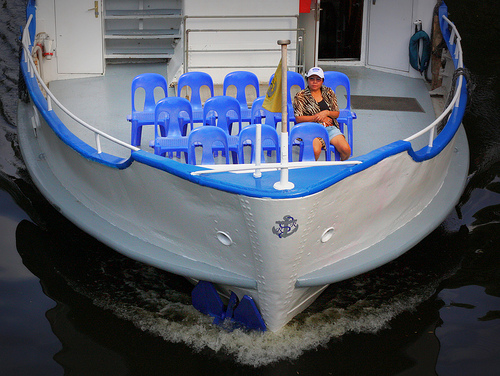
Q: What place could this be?
A: It is a river.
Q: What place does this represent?
A: It represents the river.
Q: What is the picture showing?
A: It is showing a river.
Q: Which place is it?
A: It is a river.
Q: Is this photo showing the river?
A: Yes, it is showing the river.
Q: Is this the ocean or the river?
A: It is the river.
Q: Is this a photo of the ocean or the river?
A: It is showing the river.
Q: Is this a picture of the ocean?
A: No, the picture is showing the river.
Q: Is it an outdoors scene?
A: Yes, it is outdoors.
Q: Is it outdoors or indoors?
A: It is outdoors.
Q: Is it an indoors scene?
A: No, it is outdoors.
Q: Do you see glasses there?
A: No, there are no glasses.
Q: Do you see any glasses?
A: No, there are no glasses.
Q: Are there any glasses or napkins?
A: No, there are no glasses or napkins.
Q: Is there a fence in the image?
A: No, there are no fences.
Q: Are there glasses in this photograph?
A: No, there are no glasses.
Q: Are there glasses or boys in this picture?
A: No, there are no glasses or boys.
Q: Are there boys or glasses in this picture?
A: No, there are no glasses or boys.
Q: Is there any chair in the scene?
A: Yes, there is a chair.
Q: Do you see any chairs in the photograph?
A: Yes, there is a chair.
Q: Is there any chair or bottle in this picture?
A: Yes, there is a chair.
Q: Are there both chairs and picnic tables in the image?
A: No, there is a chair but no picnic tables.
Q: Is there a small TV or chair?
A: Yes, there is a small chair.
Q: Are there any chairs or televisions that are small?
A: Yes, the chair is small.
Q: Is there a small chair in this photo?
A: Yes, there is a small chair.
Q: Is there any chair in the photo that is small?
A: Yes, there is a chair that is small.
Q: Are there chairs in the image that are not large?
A: Yes, there is a small chair.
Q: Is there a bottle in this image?
A: No, there are no bottles.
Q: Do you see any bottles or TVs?
A: No, there are no bottles or tvs.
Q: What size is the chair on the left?
A: The chair is small.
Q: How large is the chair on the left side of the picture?
A: The chair is small.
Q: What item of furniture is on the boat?
A: The piece of furniture is a chair.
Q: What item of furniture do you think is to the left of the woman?
A: The piece of furniture is a chair.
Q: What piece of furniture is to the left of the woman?
A: The piece of furniture is a chair.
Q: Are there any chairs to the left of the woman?
A: Yes, there is a chair to the left of the woman.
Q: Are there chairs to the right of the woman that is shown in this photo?
A: No, the chair is to the left of the woman.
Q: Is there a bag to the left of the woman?
A: No, there is a chair to the left of the woman.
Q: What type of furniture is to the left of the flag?
A: The piece of furniture is a chair.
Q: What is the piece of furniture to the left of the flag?
A: The piece of furniture is a chair.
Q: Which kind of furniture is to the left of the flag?
A: The piece of furniture is a chair.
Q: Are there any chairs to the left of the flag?
A: Yes, there is a chair to the left of the flag.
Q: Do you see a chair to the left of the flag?
A: Yes, there is a chair to the left of the flag.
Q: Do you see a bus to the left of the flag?
A: No, there is a chair to the left of the flag.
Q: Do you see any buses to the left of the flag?
A: No, there is a chair to the left of the flag.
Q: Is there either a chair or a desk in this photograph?
A: Yes, there is a chair.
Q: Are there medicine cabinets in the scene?
A: No, there are no medicine cabinets.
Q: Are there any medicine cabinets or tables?
A: No, there are no medicine cabinets or tables.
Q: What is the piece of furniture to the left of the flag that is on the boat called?
A: The piece of furniture is a chair.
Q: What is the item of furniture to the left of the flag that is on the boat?
A: The piece of furniture is a chair.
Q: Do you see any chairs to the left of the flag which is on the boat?
A: Yes, there is a chair to the left of the flag.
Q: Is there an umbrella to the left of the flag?
A: No, there is a chair to the left of the flag.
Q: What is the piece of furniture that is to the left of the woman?
A: The piece of furniture is a chair.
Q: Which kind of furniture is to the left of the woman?
A: The piece of furniture is a chair.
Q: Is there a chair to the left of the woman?
A: Yes, there is a chair to the left of the woman.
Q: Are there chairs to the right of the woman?
A: No, the chair is to the left of the woman.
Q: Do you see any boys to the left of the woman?
A: No, there is a chair to the left of the woman.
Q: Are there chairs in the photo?
A: Yes, there is a chair.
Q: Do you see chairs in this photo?
A: Yes, there is a chair.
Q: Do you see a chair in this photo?
A: Yes, there is a chair.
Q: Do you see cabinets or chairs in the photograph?
A: Yes, there is a chair.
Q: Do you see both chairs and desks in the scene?
A: No, there is a chair but no desks.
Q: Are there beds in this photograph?
A: No, there are no beds.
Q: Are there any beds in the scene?
A: No, there are no beds.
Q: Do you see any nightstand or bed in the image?
A: No, there are no beds or nightstands.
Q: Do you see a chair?
A: Yes, there is a chair.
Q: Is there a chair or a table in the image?
A: Yes, there is a chair.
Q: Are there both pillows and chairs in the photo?
A: No, there is a chair but no pillows.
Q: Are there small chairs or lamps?
A: Yes, there is a small chair.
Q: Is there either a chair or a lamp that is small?
A: Yes, the chair is small.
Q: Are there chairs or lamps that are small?
A: Yes, the chair is small.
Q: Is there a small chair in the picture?
A: Yes, there is a small chair.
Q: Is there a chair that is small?
A: Yes, there is a chair that is small.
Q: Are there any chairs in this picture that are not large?
A: Yes, there is a small chair.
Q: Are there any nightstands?
A: No, there are no nightstands.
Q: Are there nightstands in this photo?
A: No, there are no nightstands.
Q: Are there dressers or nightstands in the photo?
A: No, there are no nightstands or dressers.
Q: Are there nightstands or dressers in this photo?
A: No, there are no nightstands or dressers.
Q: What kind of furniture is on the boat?
A: The piece of furniture is a chair.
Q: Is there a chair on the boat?
A: Yes, there is a chair on the boat.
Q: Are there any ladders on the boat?
A: No, there is a chair on the boat.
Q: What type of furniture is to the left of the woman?
A: The piece of furniture is a chair.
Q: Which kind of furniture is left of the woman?
A: The piece of furniture is a chair.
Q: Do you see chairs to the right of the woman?
A: No, the chair is to the left of the woman.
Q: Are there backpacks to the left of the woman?
A: No, there is a chair to the left of the woman.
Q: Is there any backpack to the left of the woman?
A: No, there is a chair to the left of the woman.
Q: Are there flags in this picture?
A: Yes, there is a flag.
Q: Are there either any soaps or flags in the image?
A: Yes, there is a flag.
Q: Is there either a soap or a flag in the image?
A: Yes, there is a flag.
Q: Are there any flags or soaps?
A: Yes, there is a flag.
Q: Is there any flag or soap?
A: Yes, there is a flag.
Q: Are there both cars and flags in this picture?
A: No, there is a flag but no cars.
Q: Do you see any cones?
A: No, there are no cones.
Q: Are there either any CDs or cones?
A: No, there are no cones or cds.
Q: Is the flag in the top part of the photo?
A: Yes, the flag is in the top of the image.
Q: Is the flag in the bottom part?
A: No, the flag is in the top of the image.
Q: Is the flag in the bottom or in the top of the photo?
A: The flag is in the top of the image.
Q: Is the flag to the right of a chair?
A: Yes, the flag is to the right of a chair.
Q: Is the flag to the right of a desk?
A: No, the flag is to the right of a chair.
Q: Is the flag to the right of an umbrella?
A: No, the flag is to the right of a chair.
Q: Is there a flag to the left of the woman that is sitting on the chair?
A: Yes, there is a flag to the left of the woman.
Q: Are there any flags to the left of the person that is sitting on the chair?
A: Yes, there is a flag to the left of the woman.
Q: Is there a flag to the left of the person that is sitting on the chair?
A: Yes, there is a flag to the left of the woman.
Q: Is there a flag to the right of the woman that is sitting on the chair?
A: No, the flag is to the left of the woman.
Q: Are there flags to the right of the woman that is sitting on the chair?
A: No, the flag is to the left of the woman.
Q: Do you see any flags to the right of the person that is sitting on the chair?
A: No, the flag is to the left of the woman.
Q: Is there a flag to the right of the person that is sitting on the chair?
A: No, the flag is to the left of the woman.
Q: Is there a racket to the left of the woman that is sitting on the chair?
A: No, there is a flag to the left of the woman.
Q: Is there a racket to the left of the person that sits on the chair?
A: No, there is a flag to the left of the woman.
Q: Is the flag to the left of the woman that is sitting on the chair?
A: Yes, the flag is to the left of the woman.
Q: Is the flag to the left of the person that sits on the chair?
A: Yes, the flag is to the left of the woman.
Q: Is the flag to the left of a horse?
A: No, the flag is to the left of the woman.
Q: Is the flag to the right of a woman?
A: No, the flag is to the left of a woman.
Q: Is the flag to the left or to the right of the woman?
A: The flag is to the left of the woman.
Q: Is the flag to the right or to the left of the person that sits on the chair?
A: The flag is to the left of the woman.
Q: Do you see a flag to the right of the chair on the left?
A: Yes, there is a flag to the right of the chair.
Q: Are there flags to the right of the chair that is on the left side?
A: Yes, there is a flag to the right of the chair.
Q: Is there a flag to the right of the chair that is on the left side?
A: Yes, there is a flag to the right of the chair.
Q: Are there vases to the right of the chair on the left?
A: No, there is a flag to the right of the chair.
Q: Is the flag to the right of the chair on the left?
A: Yes, the flag is to the right of the chair.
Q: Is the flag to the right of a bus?
A: No, the flag is to the right of the chair.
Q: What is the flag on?
A: The flag is on the boat.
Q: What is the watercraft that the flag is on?
A: The watercraft is a boat.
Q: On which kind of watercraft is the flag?
A: The flag is on the boat.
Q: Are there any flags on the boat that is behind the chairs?
A: Yes, there is a flag on the boat.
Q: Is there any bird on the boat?
A: No, there is a flag on the boat.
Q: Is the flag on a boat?
A: Yes, the flag is on a boat.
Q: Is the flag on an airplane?
A: No, the flag is on a boat.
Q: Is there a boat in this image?
A: Yes, there is a boat.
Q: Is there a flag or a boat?
A: Yes, there is a boat.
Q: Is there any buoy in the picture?
A: No, there are no buoys.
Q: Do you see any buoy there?
A: No, there are no buoys.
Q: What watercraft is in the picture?
A: The watercraft is a boat.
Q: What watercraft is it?
A: The watercraft is a boat.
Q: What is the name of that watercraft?
A: That is a boat.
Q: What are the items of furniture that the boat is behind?
A: The pieces of furniture are chairs.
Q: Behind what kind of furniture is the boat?
A: The boat is behind the chairs.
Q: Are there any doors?
A: Yes, there is a door.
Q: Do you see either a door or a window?
A: Yes, there is a door.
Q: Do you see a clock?
A: No, there are no clocks.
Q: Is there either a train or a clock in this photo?
A: No, there are no clocks or trains.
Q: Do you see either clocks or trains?
A: No, there are no clocks or trains.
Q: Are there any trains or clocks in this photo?
A: No, there are no clocks or trains.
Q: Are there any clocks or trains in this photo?
A: No, there are no clocks or trains.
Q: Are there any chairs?
A: Yes, there is a chair.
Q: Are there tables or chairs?
A: Yes, there is a chair.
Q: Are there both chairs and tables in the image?
A: No, there is a chair but no tables.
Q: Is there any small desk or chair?
A: Yes, there is a small chair.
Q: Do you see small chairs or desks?
A: Yes, there is a small chair.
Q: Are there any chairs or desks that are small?
A: Yes, the chair is small.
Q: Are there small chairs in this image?
A: Yes, there is a small chair.